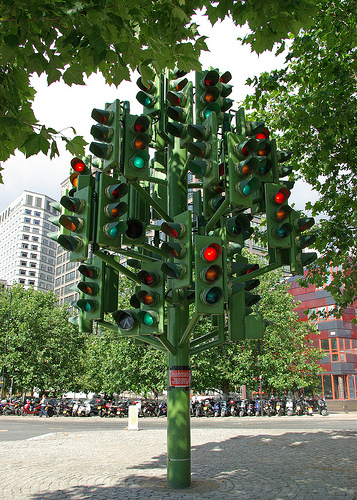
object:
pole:
[166, 92, 191, 490]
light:
[46, 69, 317, 489]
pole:
[205, 197, 230, 233]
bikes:
[0, 392, 327, 417]